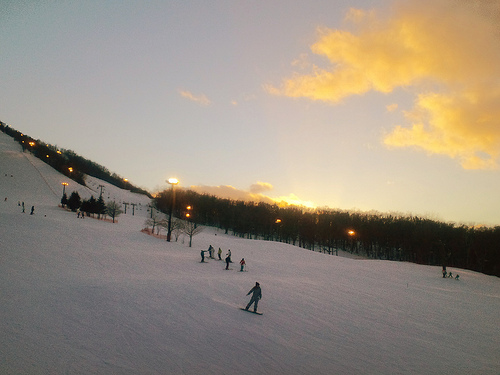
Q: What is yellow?
A: Cloud.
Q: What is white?
A: Snow.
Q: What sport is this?
A: Snowboarding.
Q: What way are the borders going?
A: Downhill.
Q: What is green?
A: Trees.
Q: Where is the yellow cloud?
A: In the sky.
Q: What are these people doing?
A: Skiing.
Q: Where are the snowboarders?
A: On a ski slope.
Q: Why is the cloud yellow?
A: The sun is setting.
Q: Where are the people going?
A: Downhill.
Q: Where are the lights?
A: Along the ski slope.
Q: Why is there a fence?
A: So people do not hit the trees.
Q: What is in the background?
A: Trees.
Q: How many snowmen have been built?
A: None.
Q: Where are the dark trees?
A: In the background on the right.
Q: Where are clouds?
A: In the sky.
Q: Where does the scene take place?
A: At a ski slope.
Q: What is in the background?
A: Trees.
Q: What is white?
A: Snow.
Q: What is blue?
A: Sky.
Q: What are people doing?
A: Snowboarding.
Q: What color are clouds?
A: White.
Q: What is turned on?
A: Lights.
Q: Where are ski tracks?
A: On the snow.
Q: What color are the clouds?
A: Yellow.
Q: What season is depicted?
A: Winter.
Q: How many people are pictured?
A: Sixteen.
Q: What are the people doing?
A: Skiing.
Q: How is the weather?
A: Cold.